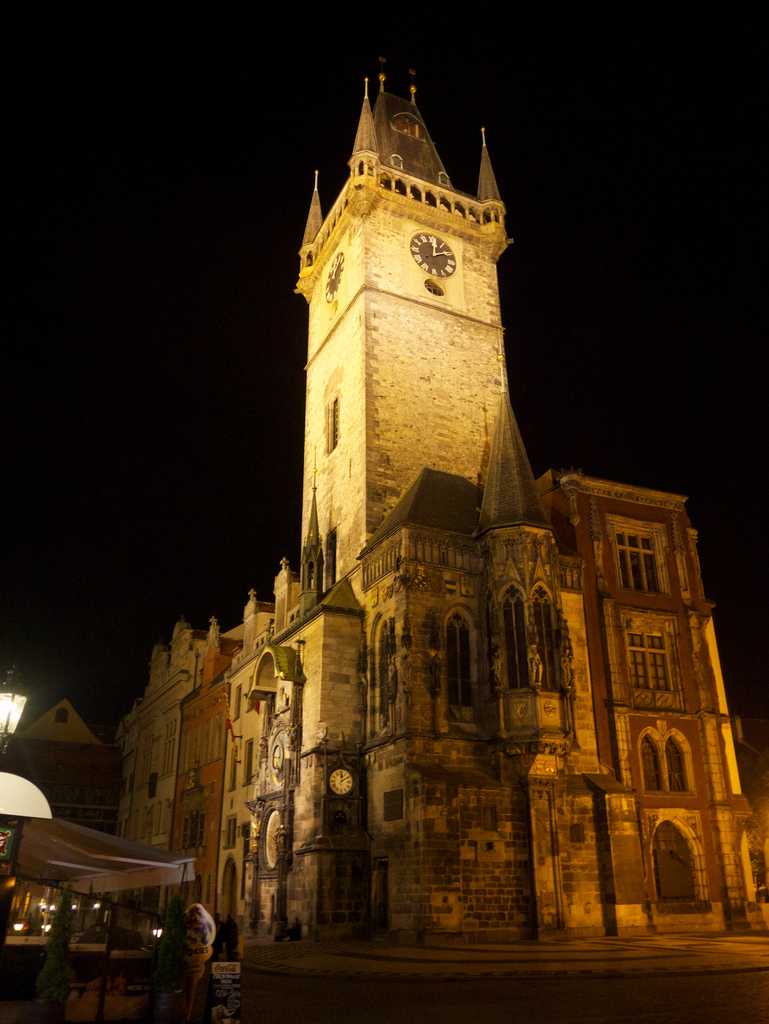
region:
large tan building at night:
[126, 58, 760, 950]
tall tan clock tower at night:
[247, 67, 539, 464]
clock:
[390, 215, 458, 289]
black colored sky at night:
[49, 157, 125, 250]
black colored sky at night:
[28, 397, 80, 445]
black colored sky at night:
[162, 423, 191, 455]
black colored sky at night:
[606, 336, 652, 398]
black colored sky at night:
[574, 171, 633, 222]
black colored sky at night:
[152, 268, 216, 353]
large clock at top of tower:
[402, 222, 461, 283]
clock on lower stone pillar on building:
[324, 760, 358, 805]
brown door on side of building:
[646, 814, 706, 907]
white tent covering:
[1, 804, 200, 905]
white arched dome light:
[0, 766, 56, 831]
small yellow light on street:
[6, 918, 31, 935]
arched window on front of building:
[632, 724, 669, 801]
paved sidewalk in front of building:
[246, 926, 767, 987]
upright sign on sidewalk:
[200, 957, 249, 1022]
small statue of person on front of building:
[521, 635, 548, 694]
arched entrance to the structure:
[653, 818, 693, 898]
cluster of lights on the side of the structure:
[12, 896, 161, 938]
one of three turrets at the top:
[346, 71, 393, 220]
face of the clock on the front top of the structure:
[405, 229, 456, 275]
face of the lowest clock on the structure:
[326, 770, 356, 796]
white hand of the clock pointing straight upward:
[430, 241, 438, 259]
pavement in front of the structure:
[235, 975, 767, 1022]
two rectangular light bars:
[1, 691, 28, 734]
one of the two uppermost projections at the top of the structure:
[373, 48, 389, 88]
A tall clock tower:
[295, 53, 514, 602]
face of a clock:
[407, 228, 455, 276]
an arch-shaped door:
[650, 816, 697, 903]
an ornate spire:
[473, 335, 547, 530]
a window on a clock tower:
[325, 393, 343, 451]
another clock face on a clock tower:
[325, 254, 345, 302]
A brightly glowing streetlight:
[0, 656, 25, 772]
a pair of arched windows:
[630, 716, 697, 799]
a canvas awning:
[0, 813, 196, 903]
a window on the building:
[613, 640, 656, 686]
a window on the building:
[617, 719, 689, 806]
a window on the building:
[511, 610, 526, 660]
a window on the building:
[542, 572, 548, 692]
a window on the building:
[349, 618, 417, 745]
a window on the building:
[180, 812, 201, 858]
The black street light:
[3, 683, 34, 745]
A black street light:
[0, 662, 36, 747]